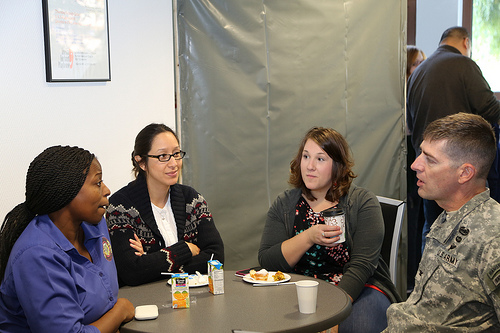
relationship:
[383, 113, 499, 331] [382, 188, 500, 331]
man wearing military uniform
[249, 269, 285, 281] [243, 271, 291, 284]
food on top of plate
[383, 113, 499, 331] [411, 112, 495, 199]
man has head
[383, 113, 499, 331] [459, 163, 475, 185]
man has ear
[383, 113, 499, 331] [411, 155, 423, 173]
man has nose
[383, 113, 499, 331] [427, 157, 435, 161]
man has eye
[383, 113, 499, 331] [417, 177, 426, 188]
man has mouth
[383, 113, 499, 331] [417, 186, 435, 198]
man has chin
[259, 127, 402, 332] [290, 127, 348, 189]
woman has head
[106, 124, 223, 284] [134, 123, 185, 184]
woman has head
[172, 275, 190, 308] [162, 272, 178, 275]
juice carton has straw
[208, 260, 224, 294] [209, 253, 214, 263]
juice carton has straw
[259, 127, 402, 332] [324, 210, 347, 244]
woman holding cup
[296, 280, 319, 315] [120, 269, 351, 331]
cup sitting on top of table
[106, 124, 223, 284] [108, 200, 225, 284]
woman crossing arms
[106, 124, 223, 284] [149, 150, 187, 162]
woman wearing glasses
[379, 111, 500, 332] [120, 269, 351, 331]
man sitting at table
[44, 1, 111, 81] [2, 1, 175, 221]
picture hanging on wall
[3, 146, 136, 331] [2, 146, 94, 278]
woman has braided hair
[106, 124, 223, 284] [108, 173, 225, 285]
woman wearing sweater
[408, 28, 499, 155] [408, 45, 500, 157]
man wearing shirt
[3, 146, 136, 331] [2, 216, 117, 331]
woman wearing shirt